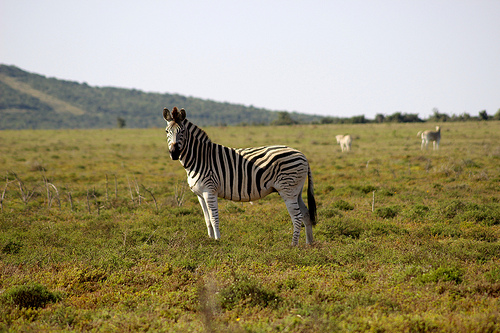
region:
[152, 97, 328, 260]
black and white striped zebra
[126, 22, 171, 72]
white clouds in blue sky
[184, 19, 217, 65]
white clouds in blue sky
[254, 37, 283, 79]
white clouds in blue sky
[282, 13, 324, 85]
white clouds in blue sky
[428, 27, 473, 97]
white clouds in blue sky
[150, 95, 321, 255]
Zebra is standing in the foreground.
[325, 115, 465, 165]
Lions are stalking in the background.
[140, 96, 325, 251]
Black and white zebra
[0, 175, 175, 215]
Dry tree branches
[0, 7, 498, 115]
Grey, overcast skies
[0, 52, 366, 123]
Dark grey hills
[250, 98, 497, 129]
Distant green bushes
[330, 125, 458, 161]
small tan lions in the distance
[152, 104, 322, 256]
Large black and white striped zebra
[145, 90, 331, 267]
A zebra standing in a field.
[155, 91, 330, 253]
A zebra looking toward the camera.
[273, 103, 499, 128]
Trees in the background.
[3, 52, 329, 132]
A hill in the background.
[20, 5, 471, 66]
Blue sky with no clouds.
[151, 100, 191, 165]
The head of a zebra.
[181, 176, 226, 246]
The front legs of a zebra.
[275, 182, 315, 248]
The back legs of a zebra.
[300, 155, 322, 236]
The tail of a zebra.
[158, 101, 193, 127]
The ears of a zebra.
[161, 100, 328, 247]
The zebra is black and white.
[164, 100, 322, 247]
The zebra has stripes.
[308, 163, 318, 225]
The zebra's tail is black.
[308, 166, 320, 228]
The zebra's tail is long.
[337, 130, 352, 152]
The animal in the background is white.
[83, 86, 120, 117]
The hill in the background is green.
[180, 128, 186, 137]
The zebra's eye is black.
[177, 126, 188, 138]
The zebra's eye is small.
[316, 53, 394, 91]
The sky is clear.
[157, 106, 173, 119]
The zebra's ear is dark in color.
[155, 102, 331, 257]
Zebra staring towards camera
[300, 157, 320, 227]
Zebra's tail swing in the air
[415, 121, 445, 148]
Llama in the backround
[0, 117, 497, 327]
Grassy field in the wilderness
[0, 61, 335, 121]
Backround mountain with many trees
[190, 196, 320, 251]
Zebra's legs with hooves hidden by grass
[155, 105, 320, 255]
Zebra looking into yonder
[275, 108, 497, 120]
Trees in the distance back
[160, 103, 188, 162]
Head of a zebra noticing something odd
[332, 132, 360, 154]
White llama grazing in the pasture